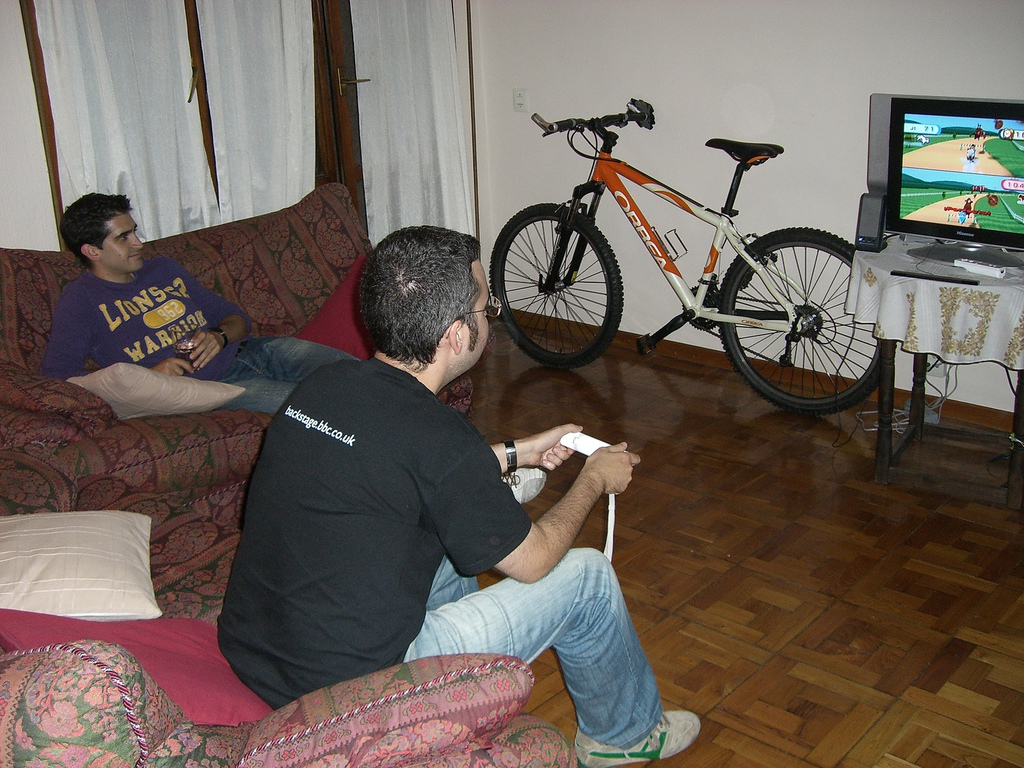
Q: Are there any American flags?
A: No, there are no American flags.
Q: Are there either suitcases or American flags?
A: No, there are no American flags or suitcases.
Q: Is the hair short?
A: Yes, the hair is short.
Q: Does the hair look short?
A: Yes, the hair is short.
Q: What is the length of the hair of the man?
A: The hair is short.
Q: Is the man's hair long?
A: No, the hair is short.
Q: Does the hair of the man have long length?
A: No, the hair is short.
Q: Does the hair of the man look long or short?
A: The hair is short.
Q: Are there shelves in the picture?
A: No, there are no shelves.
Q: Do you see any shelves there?
A: No, there are no shelves.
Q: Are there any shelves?
A: No, there are no shelves.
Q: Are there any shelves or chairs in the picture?
A: No, there are no shelves or chairs.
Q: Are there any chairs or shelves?
A: No, there are no shelves or chairs.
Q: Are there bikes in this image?
A: Yes, there is a bike.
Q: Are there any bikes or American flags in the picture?
A: Yes, there is a bike.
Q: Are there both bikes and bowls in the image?
A: No, there is a bike but no bowls.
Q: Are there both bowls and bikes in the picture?
A: No, there is a bike but no bowls.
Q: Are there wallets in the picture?
A: No, there are no wallets.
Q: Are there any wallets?
A: No, there are no wallets.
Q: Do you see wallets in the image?
A: No, there are no wallets.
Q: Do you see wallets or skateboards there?
A: No, there are no wallets or skateboards.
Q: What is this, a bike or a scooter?
A: This is a bike.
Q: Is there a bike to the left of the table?
A: Yes, there is a bike to the left of the table.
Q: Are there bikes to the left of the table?
A: Yes, there is a bike to the left of the table.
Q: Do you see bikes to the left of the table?
A: Yes, there is a bike to the left of the table.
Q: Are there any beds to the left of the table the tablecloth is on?
A: No, there is a bike to the left of the table.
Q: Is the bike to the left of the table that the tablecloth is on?
A: Yes, the bike is to the left of the table.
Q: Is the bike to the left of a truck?
A: No, the bike is to the left of the table.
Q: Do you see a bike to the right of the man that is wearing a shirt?
A: Yes, there is a bike to the right of the man.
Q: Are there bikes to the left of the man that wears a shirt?
A: No, the bike is to the right of the man.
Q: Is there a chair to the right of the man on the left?
A: No, there is a bike to the right of the man.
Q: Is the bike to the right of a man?
A: Yes, the bike is to the right of a man.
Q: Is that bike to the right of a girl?
A: No, the bike is to the right of a man.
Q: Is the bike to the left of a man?
A: No, the bike is to the right of a man.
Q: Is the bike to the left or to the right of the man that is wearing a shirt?
A: The bike is to the right of the man.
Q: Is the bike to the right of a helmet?
A: No, the bike is to the right of the pillow.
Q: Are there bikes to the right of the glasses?
A: Yes, there is a bike to the right of the glasses.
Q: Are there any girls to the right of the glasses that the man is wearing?
A: No, there is a bike to the right of the glasses.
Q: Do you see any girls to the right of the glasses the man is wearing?
A: No, there is a bike to the right of the glasses.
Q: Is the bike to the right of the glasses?
A: Yes, the bike is to the right of the glasses.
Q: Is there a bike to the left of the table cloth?
A: Yes, there is a bike to the left of the table cloth.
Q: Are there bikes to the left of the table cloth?
A: Yes, there is a bike to the left of the table cloth.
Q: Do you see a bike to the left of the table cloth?
A: Yes, there is a bike to the left of the table cloth.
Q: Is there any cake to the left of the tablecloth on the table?
A: No, there is a bike to the left of the tablecloth.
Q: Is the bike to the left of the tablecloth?
A: Yes, the bike is to the left of the tablecloth.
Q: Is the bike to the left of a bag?
A: No, the bike is to the left of the tablecloth.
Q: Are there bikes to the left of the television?
A: Yes, there is a bike to the left of the television.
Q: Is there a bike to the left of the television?
A: Yes, there is a bike to the left of the television.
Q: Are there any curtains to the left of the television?
A: No, there is a bike to the left of the television.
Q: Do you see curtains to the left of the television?
A: No, there is a bike to the left of the television.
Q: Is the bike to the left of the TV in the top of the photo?
A: Yes, the bike is to the left of the TV.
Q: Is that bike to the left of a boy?
A: No, the bike is to the left of the TV.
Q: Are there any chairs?
A: No, there are no chairs.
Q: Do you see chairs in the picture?
A: No, there are no chairs.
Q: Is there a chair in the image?
A: No, there are no chairs.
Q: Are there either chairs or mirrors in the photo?
A: No, there are no chairs or mirrors.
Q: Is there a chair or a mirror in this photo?
A: No, there are no chairs or mirrors.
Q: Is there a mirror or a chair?
A: No, there are no chairs or mirrors.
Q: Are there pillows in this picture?
A: Yes, there is a pillow.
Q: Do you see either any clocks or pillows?
A: Yes, there is a pillow.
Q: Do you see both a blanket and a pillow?
A: No, there is a pillow but no blankets.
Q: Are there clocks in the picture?
A: No, there are no clocks.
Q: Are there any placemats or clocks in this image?
A: No, there are no clocks or placemats.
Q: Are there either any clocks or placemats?
A: No, there are no clocks or placemats.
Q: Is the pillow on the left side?
A: Yes, the pillow is on the left of the image.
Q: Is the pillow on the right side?
A: No, the pillow is on the left of the image.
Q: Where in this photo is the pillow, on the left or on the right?
A: The pillow is on the left of the image.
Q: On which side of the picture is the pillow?
A: The pillow is on the left of the image.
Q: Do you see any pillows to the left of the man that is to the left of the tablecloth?
A: Yes, there is a pillow to the left of the man.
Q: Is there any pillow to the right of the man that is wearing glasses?
A: No, the pillow is to the left of the man.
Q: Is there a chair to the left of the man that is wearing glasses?
A: No, there is a pillow to the left of the man.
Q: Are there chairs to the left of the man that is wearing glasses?
A: No, there is a pillow to the left of the man.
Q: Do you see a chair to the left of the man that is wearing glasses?
A: No, there is a pillow to the left of the man.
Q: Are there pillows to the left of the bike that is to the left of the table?
A: Yes, there is a pillow to the left of the bike.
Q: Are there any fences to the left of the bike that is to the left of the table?
A: No, there is a pillow to the left of the bike.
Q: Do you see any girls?
A: No, there are no girls.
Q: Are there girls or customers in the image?
A: No, there are no girls or customers.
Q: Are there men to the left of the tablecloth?
A: Yes, there is a man to the left of the tablecloth.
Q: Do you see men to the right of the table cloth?
A: No, the man is to the left of the table cloth.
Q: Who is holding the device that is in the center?
A: The man is holding the controller.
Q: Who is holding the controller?
A: The man is holding the controller.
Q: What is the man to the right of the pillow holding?
A: The man is holding the controller.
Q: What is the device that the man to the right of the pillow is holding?
A: The device is a controller.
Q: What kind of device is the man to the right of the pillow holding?
A: The man is holding the controller.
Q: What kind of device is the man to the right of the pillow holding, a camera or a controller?
A: The man is holding a controller.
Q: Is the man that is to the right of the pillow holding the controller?
A: Yes, the man is holding the controller.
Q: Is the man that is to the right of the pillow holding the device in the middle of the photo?
A: Yes, the man is holding the controller.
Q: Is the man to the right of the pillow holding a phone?
A: No, the man is holding the controller.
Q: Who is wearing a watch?
A: The man is wearing a watch.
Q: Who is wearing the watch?
A: The man is wearing a watch.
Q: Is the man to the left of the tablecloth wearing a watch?
A: Yes, the man is wearing a watch.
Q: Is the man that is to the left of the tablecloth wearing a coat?
A: No, the man is wearing a watch.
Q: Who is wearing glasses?
A: The man is wearing glasses.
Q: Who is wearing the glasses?
A: The man is wearing glasses.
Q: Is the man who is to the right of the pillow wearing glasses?
A: Yes, the man is wearing glasses.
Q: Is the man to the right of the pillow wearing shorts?
A: No, the man is wearing glasses.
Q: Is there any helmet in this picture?
A: No, there are no helmets.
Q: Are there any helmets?
A: No, there are no helmets.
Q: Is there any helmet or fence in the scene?
A: No, there are no helmets or fences.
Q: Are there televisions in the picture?
A: Yes, there is a television.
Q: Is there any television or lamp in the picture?
A: Yes, there is a television.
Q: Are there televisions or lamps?
A: Yes, there is a television.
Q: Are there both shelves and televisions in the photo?
A: No, there is a television but no shelves.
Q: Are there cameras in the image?
A: No, there are no cameras.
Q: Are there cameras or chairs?
A: No, there are no cameras or chairs.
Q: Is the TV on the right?
A: Yes, the TV is on the right of the image.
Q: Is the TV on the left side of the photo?
A: No, the TV is on the right of the image.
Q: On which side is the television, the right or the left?
A: The television is on the right of the image.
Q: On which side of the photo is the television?
A: The television is on the right of the image.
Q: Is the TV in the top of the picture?
A: Yes, the TV is in the top of the image.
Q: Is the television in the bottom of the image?
A: No, the television is in the top of the image.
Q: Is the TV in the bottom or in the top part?
A: The TV is in the top of the image.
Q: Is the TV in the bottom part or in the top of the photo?
A: The TV is in the top of the image.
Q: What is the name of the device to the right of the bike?
A: The device is a television.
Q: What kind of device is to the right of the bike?
A: The device is a television.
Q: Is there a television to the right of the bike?
A: Yes, there is a television to the right of the bike.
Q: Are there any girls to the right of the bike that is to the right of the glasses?
A: No, there is a television to the right of the bike.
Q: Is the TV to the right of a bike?
A: Yes, the TV is to the right of a bike.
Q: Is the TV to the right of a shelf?
A: No, the TV is to the right of a bike.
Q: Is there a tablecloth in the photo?
A: Yes, there is a tablecloth.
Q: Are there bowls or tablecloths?
A: Yes, there is a tablecloth.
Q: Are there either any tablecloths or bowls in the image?
A: Yes, there is a tablecloth.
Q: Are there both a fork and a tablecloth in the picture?
A: No, there is a tablecloth but no forks.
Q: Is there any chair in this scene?
A: No, there are no chairs.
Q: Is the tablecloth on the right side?
A: Yes, the tablecloth is on the right of the image.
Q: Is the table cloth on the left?
A: No, the table cloth is on the right of the image.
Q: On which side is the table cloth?
A: The table cloth is on the right of the image.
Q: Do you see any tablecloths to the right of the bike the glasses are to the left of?
A: Yes, there is a tablecloth to the right of the bike.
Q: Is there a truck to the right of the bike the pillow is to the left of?
A: No, there is a tablecloth to the right of the bike.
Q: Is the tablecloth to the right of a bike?
A: Yes, the tablecloth is to the right of a bike.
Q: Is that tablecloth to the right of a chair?
A: No, the tablecloth is to the right of a bike.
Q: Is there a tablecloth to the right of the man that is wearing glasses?
A: Yes, there is a tablecloth to the right of the man.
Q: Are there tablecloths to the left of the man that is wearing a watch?
A: No, the tablecloth is to the right of the man.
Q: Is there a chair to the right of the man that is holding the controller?
A: No, there is a tablecloth to the right of the man.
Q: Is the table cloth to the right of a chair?
A: No, the table cloth is to the right of a man.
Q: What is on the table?
A: The tablecloth is on the table.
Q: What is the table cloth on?
A: The table cloth is on the table.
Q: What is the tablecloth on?
A: The table cloth is on the table.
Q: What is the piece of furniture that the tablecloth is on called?
A: The piece of furniture is a table.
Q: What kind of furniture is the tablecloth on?
A: The tablecloth is on the table.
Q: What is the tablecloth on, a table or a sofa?
A: The tablecloth is on a table.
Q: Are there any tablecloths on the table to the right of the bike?
A: Yes, there is a tablecloth on the table.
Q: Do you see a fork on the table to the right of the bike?
A: No, there is a tablecloth on the table.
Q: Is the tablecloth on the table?
A: Yes, the tablecloth is on the table.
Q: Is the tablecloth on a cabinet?
A: No, the tablecloth is on the table.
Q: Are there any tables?
A: Yes, there is a table.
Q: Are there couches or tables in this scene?
A: Yes, there is a table.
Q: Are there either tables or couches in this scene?
A: Yes, there is a table.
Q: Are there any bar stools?
A: No, there are no bar stools.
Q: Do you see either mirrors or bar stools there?
A: No, there are no bar stools or mirrors.